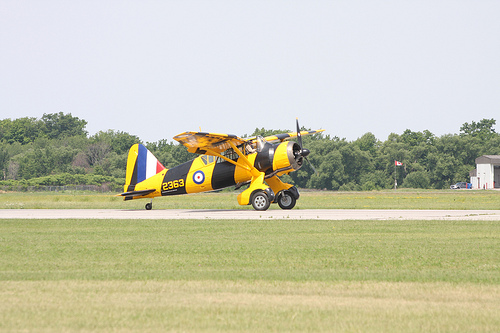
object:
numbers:
[178, 178, 185, 187]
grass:
[6, 216, 497, 283]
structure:
[469, 154, 500, 191]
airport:
[0, 117, 500, 329]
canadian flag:
[395, 160, 403, 166]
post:
[393, 159, 398, 188]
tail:
[125, 143, 167, 184]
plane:
[105, 117, 327, 213]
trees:
[457, 118, 497, 136]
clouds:
[0, 0, 500, 134]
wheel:
[251, 192, 270, 211]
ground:
[0, 218, 500, 333]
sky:
[1, 0, 500, 137]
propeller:
[295, 116, 303, 154]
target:
[192, 170, 206, 185]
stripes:
[137, 144, 147, 183]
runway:
[0, 207, 497, 222]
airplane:
[111, 115, 326, 214]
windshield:
[248, 139, 257, 151]